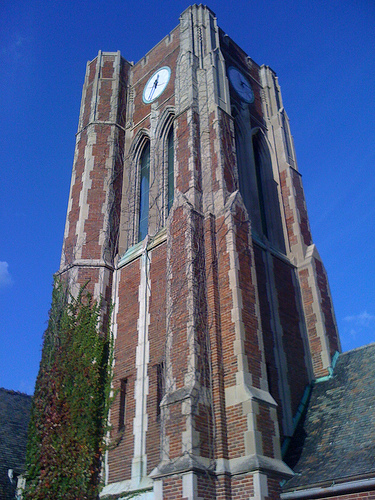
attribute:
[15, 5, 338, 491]
tower — tall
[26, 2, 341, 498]
building — old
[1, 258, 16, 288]
cloud — thin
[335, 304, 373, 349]
cloud — thin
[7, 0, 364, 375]
building — tall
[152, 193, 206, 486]
vine — sparse, winding upward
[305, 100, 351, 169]
sky — blue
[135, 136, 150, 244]
window — doubled arched, stain glass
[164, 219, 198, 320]
vine — brown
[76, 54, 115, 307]
brick — stone, mixed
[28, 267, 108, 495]
vines — green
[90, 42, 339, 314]
building — tan, old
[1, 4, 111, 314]
sky — blue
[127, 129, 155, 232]
window — tall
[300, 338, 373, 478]
roof — dark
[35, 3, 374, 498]
building — tall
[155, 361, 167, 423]
window — small, rectangular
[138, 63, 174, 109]
clock — big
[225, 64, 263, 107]
clock — big